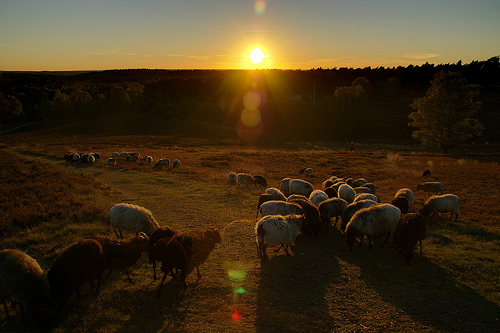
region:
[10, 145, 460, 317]
a herd of sheep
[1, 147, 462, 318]
a heard of brown and white sheep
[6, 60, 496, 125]
trees in the distance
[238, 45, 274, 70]
a yellow sun in the sky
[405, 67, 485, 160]
a green leafy green tree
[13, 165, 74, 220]
brown and green grasses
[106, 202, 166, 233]
a white sheep grazing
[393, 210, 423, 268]
a brown sheep grazing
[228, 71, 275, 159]
reflection of sunlight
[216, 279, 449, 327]
The grass is short and green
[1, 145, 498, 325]
A very large herd of sheep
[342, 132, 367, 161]
A man standing in the distance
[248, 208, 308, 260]
The sheep is the color white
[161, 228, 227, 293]
The sheep is the color black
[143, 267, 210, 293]
The legs of the sheep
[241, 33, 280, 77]
The sun is very bright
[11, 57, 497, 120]
The mountains in the distance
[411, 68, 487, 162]
The tree is very healthy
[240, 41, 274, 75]
shiny sun on sunset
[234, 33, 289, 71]
sunset in sky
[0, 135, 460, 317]
flock of sheeps on a field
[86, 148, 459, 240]
a bunch of white sheeps on a field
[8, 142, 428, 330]
a bunch of brown sheeps on a field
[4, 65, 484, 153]
small trees in the back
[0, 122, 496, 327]
big large field where sheeps are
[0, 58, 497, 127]
large mountains in the back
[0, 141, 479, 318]
flock of sheep in the sunset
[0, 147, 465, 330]
sheeps are full of wool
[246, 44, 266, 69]
Sun setting in the sky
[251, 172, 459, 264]
Sheep in a group, eating grass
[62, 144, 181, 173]
Sheep eating grass in a field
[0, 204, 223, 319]
Black and white sheep walking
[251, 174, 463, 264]
White and brown sheep eating grass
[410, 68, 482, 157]
A tree in the distance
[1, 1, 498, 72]
A sky with few clouds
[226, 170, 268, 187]
Three sheep eating grass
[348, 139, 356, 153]
A man walking in the field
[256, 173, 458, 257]
Sheep eating grass in a field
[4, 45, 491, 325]
sheep grazing in pasture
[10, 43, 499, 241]
sun setting over pasture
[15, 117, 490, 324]
sheep have full coats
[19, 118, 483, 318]
grass is lush and green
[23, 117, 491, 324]
sheep are brown and white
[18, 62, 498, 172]
trees surrounding pasture are green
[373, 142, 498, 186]
dry brush in pasture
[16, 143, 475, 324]
path created in pasture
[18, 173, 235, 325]
sheep walking in pasture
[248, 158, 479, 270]
sheep are eating grass